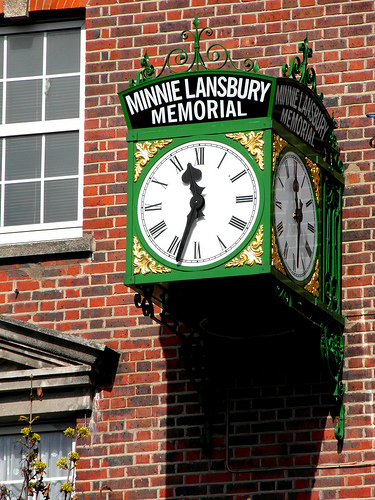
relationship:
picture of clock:
[56, 4, 358, 461] [130, 133, 261, 272]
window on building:
[1, 10, 84, 245] [0, 0, 122, 330]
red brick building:
[91, 10, 135, 32] [0, 0, 122, 330]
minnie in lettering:
[120, 79, 184, 114] [117, 72, 276, 127]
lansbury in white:
[182, 77, 270, 101] [117, 72, 276, 127]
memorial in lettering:
[150, 99, 245, 126] [117, 72, 276, 127]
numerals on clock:
[215, 149, 255, 253] [130, 133, 261, 272]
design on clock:
[226, 128, 267, 171] [130, 133, 261, 272]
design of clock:
[226, 128, 267, 171] [130, 133, 261, 272]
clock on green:
[130, 133, 261, 272] [118, 15, 276, 287]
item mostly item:
[116, 16, 344, 330] [118, 15, 276, 287]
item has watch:
[116, 16, 344, 330] [272, 121, 319, 295]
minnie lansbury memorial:
[120, 79, 184, 114] [150, 99, 245, 126]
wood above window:
[0, 116, 81, 136] [1, 10, 84, 245]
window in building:
[1, 10, 84, 245] [0, 0, 122, 330]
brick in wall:
[110, 27, 141, 38] [88, 3, 132, 84]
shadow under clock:
[155, 309, 314, 499] [130, 133, 261, 272]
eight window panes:
[1, 10, 84, 245] [5, 36, 48, 84]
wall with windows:
[1, 3, 108, 500] [0, 0, 122, 330]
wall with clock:
[56, 4, 358, 461] [130, 133, 261, 272]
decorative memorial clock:
[116, 16, 344, 330] [130, 133, 261, 272]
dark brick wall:
[94, 6, 125, 240] [88, 3, 132, 84]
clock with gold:
[130, 133, 261, 272] [226, 128, 267, 171]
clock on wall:
[130, 133, 261, 272] [116, 11, 348, 293]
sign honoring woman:
[116, 14, 274, 124] [117, 72, 276, 127]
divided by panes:
[1, 10, 84, 245] [5, 36, 48, 84]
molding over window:
[0, 315, 109, 416] [1, 434, 73, 500]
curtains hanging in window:
[1, 434, 73, 500] [3, 421, 72, 498]